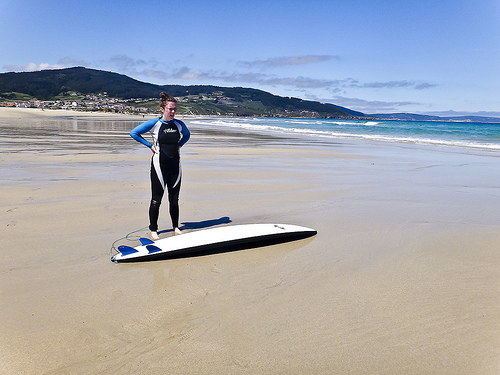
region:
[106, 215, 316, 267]
white surfboard on beach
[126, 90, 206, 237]
woman wearing black, white and blue wet suit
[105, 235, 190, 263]
three blue fins on surf board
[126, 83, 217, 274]
woman standing on sandy beach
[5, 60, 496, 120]
forested mountains in background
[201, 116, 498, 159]
waves breaking on the beach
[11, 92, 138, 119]
village at the base of the mountain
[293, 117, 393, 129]
breaker waves in the water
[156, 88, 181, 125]
woman's hair is worn up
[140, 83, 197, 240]
woman is bare foot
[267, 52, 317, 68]
clouds in the sky.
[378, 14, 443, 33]
clear blue sky above the clouds.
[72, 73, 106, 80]
green hillside above village.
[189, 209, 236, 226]
shadow on the sand.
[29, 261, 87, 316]
sand on the beach.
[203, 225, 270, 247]
white paint on surfboard.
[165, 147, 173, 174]
black wetsuit on woman.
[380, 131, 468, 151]
waves on the shore.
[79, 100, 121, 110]
buildings in the village.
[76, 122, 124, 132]
standing water on the beach.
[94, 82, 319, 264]
woman standing on beach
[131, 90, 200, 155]
woman making angry face and gestures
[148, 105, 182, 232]
woman wearing blue and black wetsuit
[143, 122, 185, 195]
blue and black wet suit has white stripes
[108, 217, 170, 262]
woman's ankle attached to surfboard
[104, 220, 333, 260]
white surfboard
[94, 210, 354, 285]
surfboard lying upside down on the sand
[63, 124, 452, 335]
sandy beach is large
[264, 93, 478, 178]
blue water in the background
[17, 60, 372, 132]
low green mountains and houses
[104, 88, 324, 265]
Woman standing by a surfboard.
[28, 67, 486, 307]
Woman standing at the beach.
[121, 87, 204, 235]
Woman wearing a white, black and blue wetsuit.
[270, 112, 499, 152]
Beautiful blue and green ocean water.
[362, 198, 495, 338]
Smooth, wet sand on the shore.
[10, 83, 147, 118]
Small beach town community.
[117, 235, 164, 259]
Three blue fins on the bottom of the surfboard.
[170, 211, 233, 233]
Shadow on the ground from the woman.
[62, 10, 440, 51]
Beautiful blue sky above.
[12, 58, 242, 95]
Rolling hilltops along the coast.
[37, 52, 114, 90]
majestic mountain range in the far off distance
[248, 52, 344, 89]
ominous storm clouds gathering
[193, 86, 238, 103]
houses dotted on the hillside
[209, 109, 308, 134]
white waves crashing towards shore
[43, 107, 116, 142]
water reflecting on the sand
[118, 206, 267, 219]
image of surfer on the sand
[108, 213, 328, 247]
surf board turned over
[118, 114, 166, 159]
neon blue sleeves of wet suit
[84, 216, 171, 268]
safety harness attached to surfer's leg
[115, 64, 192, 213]
surfer standing on the sand